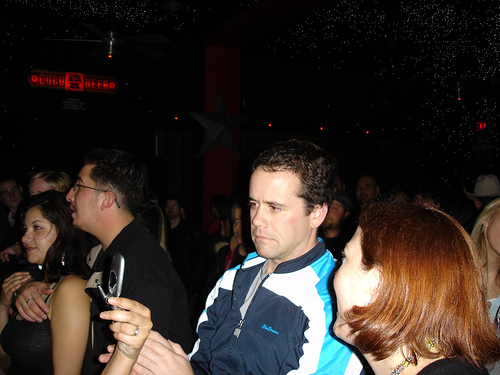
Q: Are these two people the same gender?
A: No, they are both male and female.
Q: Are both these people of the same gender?
A: No, they are both male and female.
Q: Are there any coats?
A: Yes, there is a coat.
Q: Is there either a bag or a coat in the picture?
A: Yes, there is a coat.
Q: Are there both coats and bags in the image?
A: No, there is a coat but no bags.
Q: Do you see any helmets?
A: No, there are no helmets.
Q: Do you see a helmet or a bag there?
A: No, there are no helmets or bags.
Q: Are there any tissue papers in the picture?
A: No, there are no tissue papers.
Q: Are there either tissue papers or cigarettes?
A: No, there are no tissue papers or cigarettes.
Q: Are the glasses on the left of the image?
A: Yes, the glasses are on the left of the image.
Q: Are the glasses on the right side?
A: No, the glasses are on the left of the image.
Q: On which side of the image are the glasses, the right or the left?
A: The glasses are on the left of the image.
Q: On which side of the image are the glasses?
A: The glasses are on the left of the image.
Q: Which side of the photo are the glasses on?
A: The glasses are on the left of the image.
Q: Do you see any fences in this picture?
A: No, there are no fences.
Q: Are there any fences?
A: No, there are no fences.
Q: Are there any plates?
A: No, there are no plates.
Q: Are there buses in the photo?
A: No, there are no buses.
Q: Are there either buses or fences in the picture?
A: No, there are no buses or fences.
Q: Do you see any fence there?
A: No, there are no fences.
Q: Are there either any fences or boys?
A: No, there are no fences or boys.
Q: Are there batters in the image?
A: No, there are no batters.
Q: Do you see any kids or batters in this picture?
A: No, there are no batters or kids.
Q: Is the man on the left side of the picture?
A: Yes, the man is on the left of the image.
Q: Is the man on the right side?
A: No, the man is on the left of the image.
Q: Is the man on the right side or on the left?
A: The man is on the left of the image.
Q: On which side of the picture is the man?
A: The man is on the left of the image.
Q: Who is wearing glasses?
A: The man is wearing glasses.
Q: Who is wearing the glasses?
A: The man is wearing glasses.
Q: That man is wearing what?
A: The man is wearing glasses.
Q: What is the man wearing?
A: The man is wearing glasses.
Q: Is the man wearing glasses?
A: Yes, the man is wearing glasses.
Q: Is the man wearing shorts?
A: No, the man is wearing glasses.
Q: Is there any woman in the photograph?
A: Yes, there is a woman.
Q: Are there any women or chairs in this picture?
A: Yes, there is a woman.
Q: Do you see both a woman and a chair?
A: No, there is a woman but no chairs.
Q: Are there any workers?
A: No, there are no workers.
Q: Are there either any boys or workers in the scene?
A: No, there are no workers or boys.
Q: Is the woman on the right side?
A: Yes, the woman is on the right of the image.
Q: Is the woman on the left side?
A: No, the woman is on the right of the image.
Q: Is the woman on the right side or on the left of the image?
A: The woman is on the right of the image.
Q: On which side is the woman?
A: The woman is on the right of the image.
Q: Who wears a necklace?
A: The woman wears a necklace.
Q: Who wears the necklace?
A: The woman wears a necklace.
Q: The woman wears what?
A: The woman wears a necklace.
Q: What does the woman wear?
A: The woman wears a necklace.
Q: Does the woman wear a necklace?
A: Yes, the woman wears a necklace.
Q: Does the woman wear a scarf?
A: No, the woman wears a necklace.